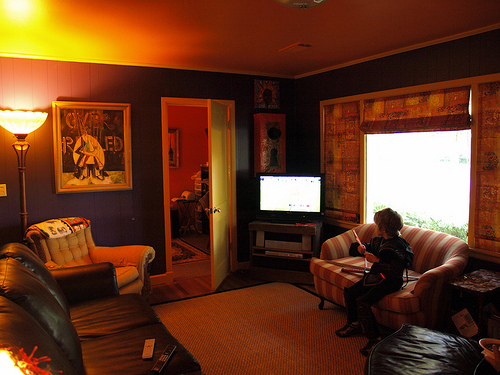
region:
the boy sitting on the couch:
[334, 208, 413, 356]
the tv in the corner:
[254, 170, 325, 216]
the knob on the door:
[212, 205, 220, 215]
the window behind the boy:
[364, 85, 472, 247]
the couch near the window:
[311, 219, 469, 329]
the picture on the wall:
[50, 100, 132, 194]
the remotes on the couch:
[141, 337, 176, 373]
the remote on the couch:
[142, 338, 156, 359]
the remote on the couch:
[152, 343, 176, 373]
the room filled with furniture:
[0, 0, 498, 373]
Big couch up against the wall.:
[323, 243, 368, 284]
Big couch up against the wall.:
[89, 324, 136, 344]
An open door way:
[160, 89, 241, 289]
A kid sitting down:
[333, 203, 413, 359]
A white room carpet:
[159, 273, 382, 373]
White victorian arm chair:
[24, 210, 169, 295]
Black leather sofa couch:
[2, 243, 203, 373]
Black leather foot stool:
[368, 315, 486, 374]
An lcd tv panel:
[261, 168, 325, 215]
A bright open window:
[362, 100, 472, 251]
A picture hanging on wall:
[53, 103, 128, 191]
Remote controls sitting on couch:
[130, 337, 186, 374]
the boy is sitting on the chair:
[321, 188, 416, 369]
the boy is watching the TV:
[222, 132, 419, 350]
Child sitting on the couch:
[330, 201, 414, 359]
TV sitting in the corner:
[253, 167, 328, 227]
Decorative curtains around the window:
[309, 71, 498, 258]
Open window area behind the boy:
[362, 123, 470, 245]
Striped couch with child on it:
[305, 218, 472, 345]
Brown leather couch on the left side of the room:
[0, 239, 206, 373]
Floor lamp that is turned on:
[0, 105, 51, 240]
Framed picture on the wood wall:
[51, 99, 136, 195]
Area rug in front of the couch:
[140, 274, 412, 373]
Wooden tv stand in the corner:
[241, 215, 326, 289]